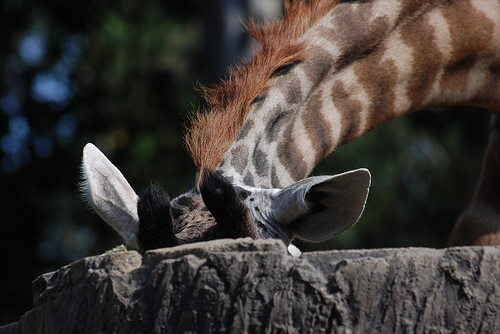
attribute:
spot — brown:
[333, 78, 367, 141]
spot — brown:
[249, 133, 271, 178]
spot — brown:
[299, 40, 336, 90]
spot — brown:
[403, 13, 439, 118]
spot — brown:
[272, 67, 320, 107]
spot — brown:
[327, 7, 383, 57]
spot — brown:
[274, 127, 309, 176]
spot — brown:
[442, 8, 483, 68]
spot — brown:
[254, 145, 265, 175]